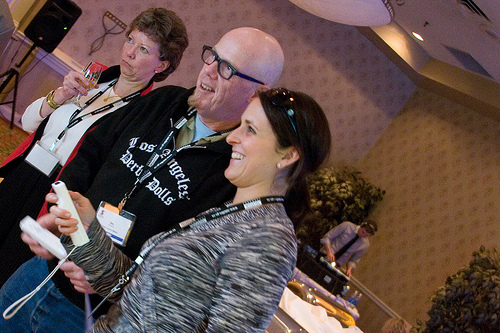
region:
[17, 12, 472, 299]
people plahying a game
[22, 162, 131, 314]
they are holding controllers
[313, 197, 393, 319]
a DJ in the background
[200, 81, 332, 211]
the lady is smiling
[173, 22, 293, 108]
this man is bald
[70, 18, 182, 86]
this lady looks unintersted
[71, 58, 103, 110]
she is holding a wine glass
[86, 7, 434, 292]
this is some kind of social event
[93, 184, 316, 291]
these people have on employee badges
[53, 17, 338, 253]
these people are at a company's function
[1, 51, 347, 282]
a man and woman holding game controllers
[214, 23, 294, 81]
a man with no hair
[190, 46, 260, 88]
a man wearing glasses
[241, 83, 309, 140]
a woman wearing sunglasses on her head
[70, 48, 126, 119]
a woman holding a wine glass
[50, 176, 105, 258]
a woman holding a game controller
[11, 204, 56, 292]
a man holding a game controller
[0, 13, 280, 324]
three people wearing name badges around their necks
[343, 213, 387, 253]
a man looking down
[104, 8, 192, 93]
a woman with short hair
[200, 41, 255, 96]
eye glasses on a man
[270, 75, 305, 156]
sunglasses on a woman's head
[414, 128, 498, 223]
ornate wallpaper on the walls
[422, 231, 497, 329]
decorative inside tree bushes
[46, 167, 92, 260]
wii mote in a woman's hand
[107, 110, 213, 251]
black jacket with white writing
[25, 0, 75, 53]
black speaker on a tripod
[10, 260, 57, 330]
blue denin jeans on a man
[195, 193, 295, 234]
black and white lanyard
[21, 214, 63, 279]
wii controller in a man's hand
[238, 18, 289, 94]
Man has bald head.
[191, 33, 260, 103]
Black glasses on man's face.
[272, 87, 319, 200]
Woman has black hair.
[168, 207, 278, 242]
Black and white lanyard around neck.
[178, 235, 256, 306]
Woman wearing black and white shirt.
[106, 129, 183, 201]
Man wearing black shirt.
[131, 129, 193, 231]
White writing on shirt.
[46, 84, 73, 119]
Gold band around woman's wrist.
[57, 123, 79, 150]
Woman wearing white shirt.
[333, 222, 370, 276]
Man wearing black tie.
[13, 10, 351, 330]
three people standing together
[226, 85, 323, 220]
the woman is smiling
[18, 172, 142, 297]
woman holding a remote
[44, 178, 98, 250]
the remote is white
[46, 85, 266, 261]
the sweatshirt is black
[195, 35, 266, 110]
man wearing glasses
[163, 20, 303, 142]
the man is bald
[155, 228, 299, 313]
the shirt is striped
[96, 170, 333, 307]
the woman is wearing a lanyard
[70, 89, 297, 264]
white writing on the black shirt